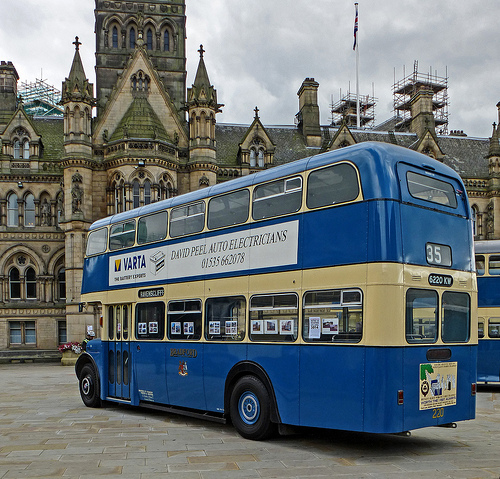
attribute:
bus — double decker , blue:
[58, 137, 480, 441]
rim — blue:
[235, 393, 262, 423]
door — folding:
[102, 298, 138, 401]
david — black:
[166, 242, 191, 265]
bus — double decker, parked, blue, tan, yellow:
[74, 141, 484, 456]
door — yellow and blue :
[110, 309, 131, 387]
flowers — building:
[51, 334, 84, 357]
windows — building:
[161, 196, 214, 240]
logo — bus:
[95, 213, 320, 283]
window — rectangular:
[392, 160, 478, 216]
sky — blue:
[1, 2, 484, 134]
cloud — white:
[216, 75, 276, 123]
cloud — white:
[185, 3, 230, 94]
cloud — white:
[218, 28, 347, 96]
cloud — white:
[308, 72, 405, 128]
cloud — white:
[24, 16, 95, 95]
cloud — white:
[20, 2, 101, 112]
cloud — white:
[207, 69, 282, 125]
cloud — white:
[185, 1, 236, 85]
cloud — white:
[202, 16, 332, 99]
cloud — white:
[318, 75, 408, 128]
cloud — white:
[31, 0, 95, 92]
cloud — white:
[207, 64, 282, 123]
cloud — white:
[207, 22, 317, 95]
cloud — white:
[322, 71, 401, 125]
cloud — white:
[186, 2, 231, 86]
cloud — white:
[203, 25, 327, 97]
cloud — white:
[35, 1, 96, 96]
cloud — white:
[0, 2, 50, 42]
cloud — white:
[185, 2, 227, 83]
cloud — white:
[203, 11, 316, 99]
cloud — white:
[207, 67, 278, 124]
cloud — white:
[30, 0, 96, 81]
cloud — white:
[203, 20, 321, 92]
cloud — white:
[234, 1, 322, 34]